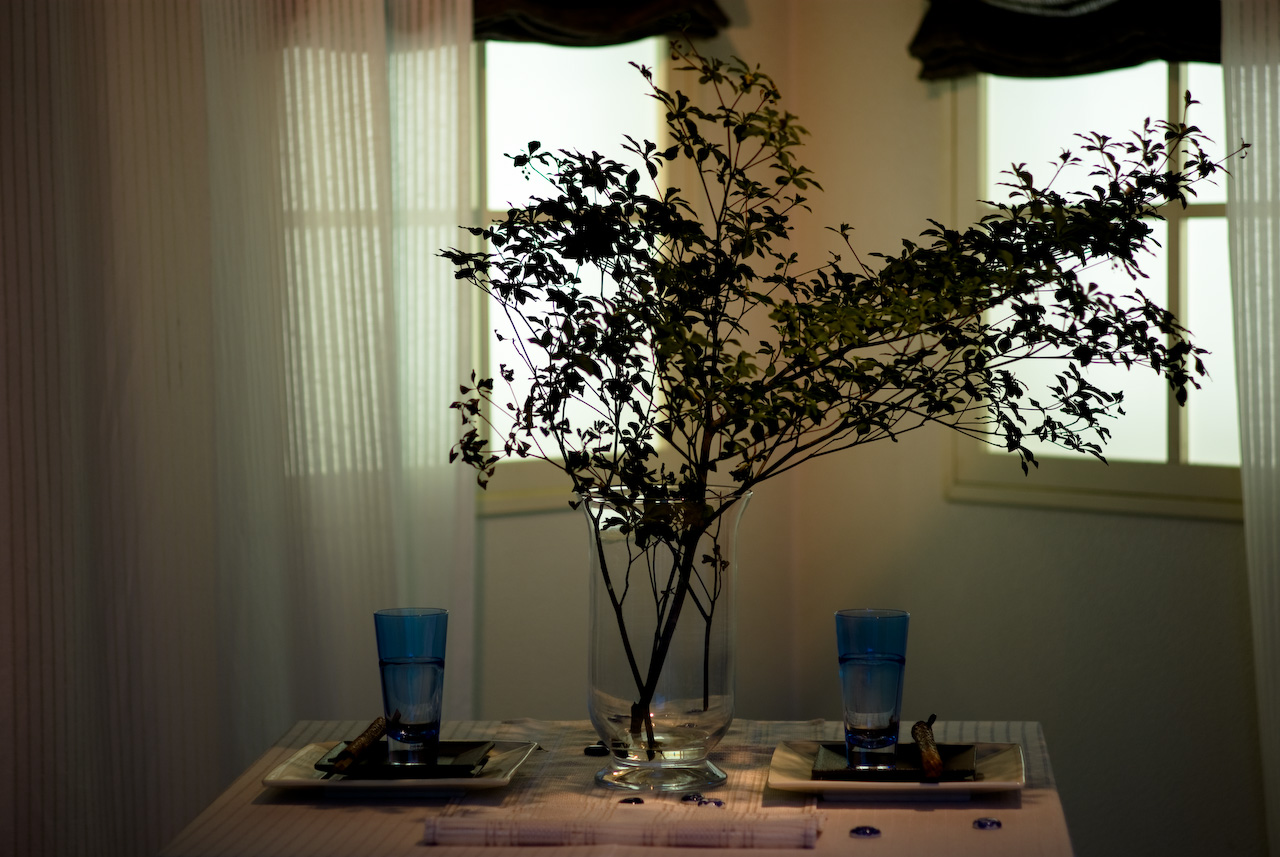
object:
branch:
[435, 40, 1246, 797]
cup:
[374, 607, 450, 765]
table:
[168, 719, 1071, 857]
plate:
[769, 742, 1026, 804]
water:
[589, 519, 732, 762]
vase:
[576, 484, 751, 794]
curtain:
[0, 0, 478, 857]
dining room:
[0, 0, 1280, 857]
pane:
[282, 18, 481, 212]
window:
[282, 37, 672, 472]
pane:
[279, 222, 481, 474]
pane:
[489, 223, 661, 464]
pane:
[482, 34, 660, 214]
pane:
[978, 60, 1168, 207]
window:
[979, 58, 1167, 205]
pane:
[1186, 62, 1280, 204]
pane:
[983, 218, 1169, 464]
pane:
[1183, 215, 1280, 467]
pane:
[835, 608, 910, 771]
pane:
[979, 61, 1279, 467]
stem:
[436, 36, 1256, 757]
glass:
[482, 33, 669, 464]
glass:
[982, 60, 1280, 468]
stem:
[578, 485, 755, 761]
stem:
[278, 36, 665, 478]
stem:
[978, 59, 1280, 469]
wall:
[285, 33, 668, 475]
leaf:
[564, 451, 599, 472]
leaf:
[621, 516, 653, 549]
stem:
[626, 462, 706, 761]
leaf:
[636, 498, 660, 537]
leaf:
[750, 394, 766, 441]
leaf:
[567, 450, 589, 475]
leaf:
[630, 442, 648, 483]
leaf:
[559, 196, 602, 252]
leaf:
[1041, 190, 1067, 211]